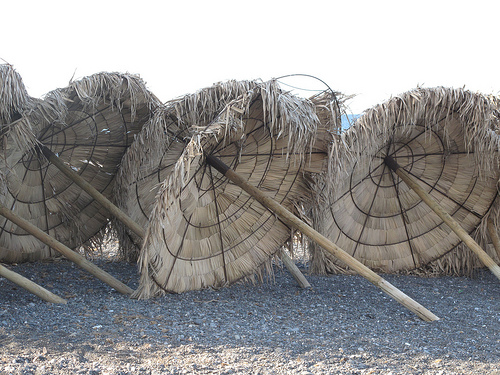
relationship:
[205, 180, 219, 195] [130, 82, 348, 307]
support on umbrella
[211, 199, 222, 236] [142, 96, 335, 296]
support on umbrella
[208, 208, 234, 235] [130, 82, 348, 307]
support on umbrella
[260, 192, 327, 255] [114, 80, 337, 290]
pole on tent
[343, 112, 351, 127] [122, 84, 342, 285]
ocean behind tents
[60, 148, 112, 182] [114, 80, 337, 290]
holes in tent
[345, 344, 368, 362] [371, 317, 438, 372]
rock in ground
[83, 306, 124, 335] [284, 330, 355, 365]
dirt in ground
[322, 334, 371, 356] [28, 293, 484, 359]
sand in beach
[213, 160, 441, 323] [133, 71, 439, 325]
post on umbrella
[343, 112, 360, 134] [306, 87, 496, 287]
ocean behind umbrella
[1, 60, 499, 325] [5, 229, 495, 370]
umbrellas laying on beach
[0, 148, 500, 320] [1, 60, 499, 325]
posts on umbrellas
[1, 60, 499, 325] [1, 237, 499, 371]
umbrellas on ground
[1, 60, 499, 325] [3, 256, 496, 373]
umbrellas in sand